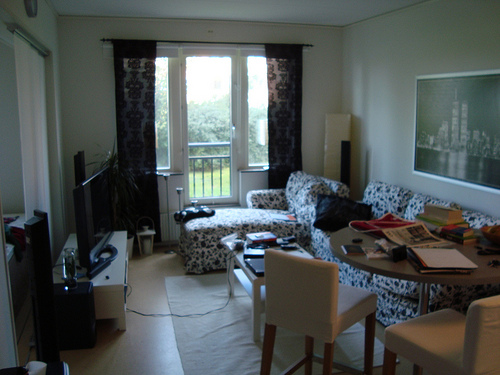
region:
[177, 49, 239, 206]
A glass door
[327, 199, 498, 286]
A round table.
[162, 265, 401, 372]
A white area rug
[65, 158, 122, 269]
A black flatscreen TV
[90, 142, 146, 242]
A house plant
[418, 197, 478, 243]
A stack of books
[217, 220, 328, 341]
A white coffee table.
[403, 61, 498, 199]
A large picture on the wall.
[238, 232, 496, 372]
Two white chairs.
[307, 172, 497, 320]
A sofa with designs on it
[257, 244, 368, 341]
the chair is white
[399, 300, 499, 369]
the chair is white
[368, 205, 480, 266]
books are on the table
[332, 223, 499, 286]
the table is round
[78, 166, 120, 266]
the tv is a flatscreen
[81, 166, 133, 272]
the tv is off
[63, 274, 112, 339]
spaeker is on the ground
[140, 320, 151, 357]
the floor is brown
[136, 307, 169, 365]
the floor is wooden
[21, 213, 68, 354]
the speakrs are surround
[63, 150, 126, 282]
the television on the stand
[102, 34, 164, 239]
the curtains are open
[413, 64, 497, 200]
the picture hanging on the wall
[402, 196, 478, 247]
the books on the table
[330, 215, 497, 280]
the table is wooden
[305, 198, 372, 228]
the pillow on the sofa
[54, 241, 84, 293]
the vase beside the television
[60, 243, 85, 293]
the vase is glass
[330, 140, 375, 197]
the speaker in the corner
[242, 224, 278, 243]
books on the coffee table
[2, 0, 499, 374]
someone's rather ordinary living room somewhere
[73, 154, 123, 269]
large flat screen television is, of course, the focal point of the room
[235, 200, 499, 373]
dining, or other use, table, now filled w/ a number of books & papers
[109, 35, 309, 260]
long dark drapes, with interesting & possibly flocked design, sheer underneath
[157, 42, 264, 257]
large door, sided on both sides by windows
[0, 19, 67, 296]
window to the side, covered by an open white curtain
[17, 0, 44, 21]
round clock above side window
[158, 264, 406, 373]
cream colour rug, long but not runner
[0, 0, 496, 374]
house seems shotgun shack shaped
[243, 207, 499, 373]
straight leg, low back chairs match the colour of the rug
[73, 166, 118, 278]
the TV is a flat screen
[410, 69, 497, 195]
framed art on the wall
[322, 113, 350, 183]
a lamp in the corner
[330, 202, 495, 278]
the table top is messy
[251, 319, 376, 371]
the chair legs are wood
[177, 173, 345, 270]
floral pattern chair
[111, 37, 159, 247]
dark decorative curtains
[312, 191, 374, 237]
a black pillow is on the couch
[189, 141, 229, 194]
the metal railing is outside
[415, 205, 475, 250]
the books are stacked